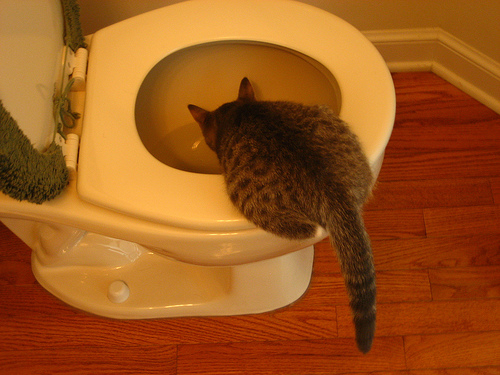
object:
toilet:
[0, 0, 398, 322]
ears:
[184, 104, 211, 127]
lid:
[0, 0, 88, 205]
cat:
[187, 77, 376, 355]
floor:
[0, 72, 500, 375]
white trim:
[425, 61, 499, 117]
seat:
[75, 0, 395, 231]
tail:
[324, 198, 377, 353]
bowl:
[134, 37, 343, 174]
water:
[165, 121, 218, 170]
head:
[183, 77, 257, 153]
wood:
[403, 329, 500, 370]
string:
[59, 105, 76, 127]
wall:
[436, 0, 500, 63]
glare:
[190, 134, 203, 150]